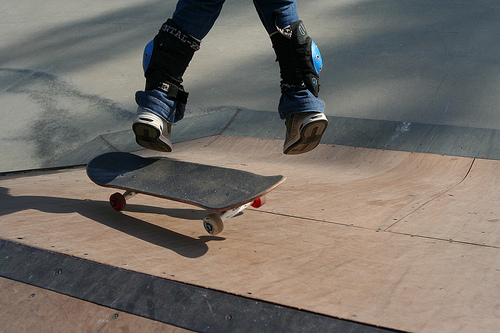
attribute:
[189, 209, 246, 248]
wheel — white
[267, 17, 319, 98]
shin guard — blue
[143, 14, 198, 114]
shin guard — blue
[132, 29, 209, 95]
pad — black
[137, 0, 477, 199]
jeans — blue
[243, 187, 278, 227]
wheel — red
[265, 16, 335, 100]
pad — protective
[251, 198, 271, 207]
wheel — red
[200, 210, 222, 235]
wheel — red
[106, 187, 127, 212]
wheel — red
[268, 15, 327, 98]
shin guard — black and blue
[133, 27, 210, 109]
shin guard — black and blue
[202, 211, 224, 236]
wheel — white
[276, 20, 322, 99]
shin guards — black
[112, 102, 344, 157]
feet — apart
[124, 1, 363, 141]
jeans — blue 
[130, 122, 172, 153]
soles — white 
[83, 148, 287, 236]
skateboard — black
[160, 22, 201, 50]
letters — white